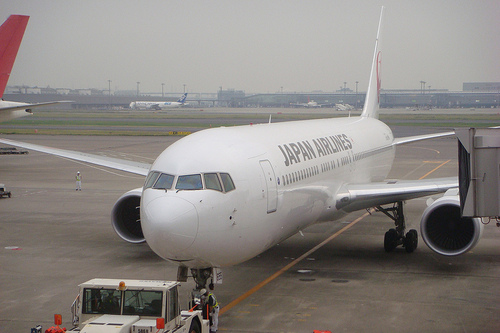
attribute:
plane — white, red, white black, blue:
[2, 3, 481, 257]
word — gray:
[275, 140, 317, 168]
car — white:
[36, 278, 212, 332]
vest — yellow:
[206, 295, 220, 309]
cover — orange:
[47, 324, 67, 332]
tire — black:
[384, 231, 395, 251]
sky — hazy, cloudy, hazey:
[1, 1, 500, 91]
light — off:
[117, 280, 128, 288]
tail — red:
[1, 14, 31, 104]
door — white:
[260, 160, 278, 214]